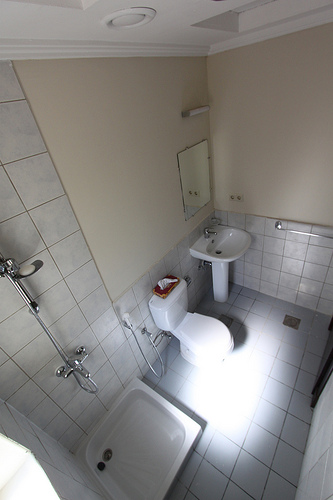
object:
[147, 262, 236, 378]
toilet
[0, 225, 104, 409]
shower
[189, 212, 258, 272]
sink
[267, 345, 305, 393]
tiles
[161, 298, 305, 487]
floor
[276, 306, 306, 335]
drain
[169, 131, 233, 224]
mirror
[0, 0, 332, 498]
all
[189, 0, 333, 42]
vent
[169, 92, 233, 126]
light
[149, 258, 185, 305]
tissue box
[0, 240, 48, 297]
shower head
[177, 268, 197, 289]
toilet paper dispens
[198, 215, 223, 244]
faucet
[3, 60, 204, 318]
wall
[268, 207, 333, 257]
bar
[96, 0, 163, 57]
light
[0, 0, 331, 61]
ceiling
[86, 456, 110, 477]
soap